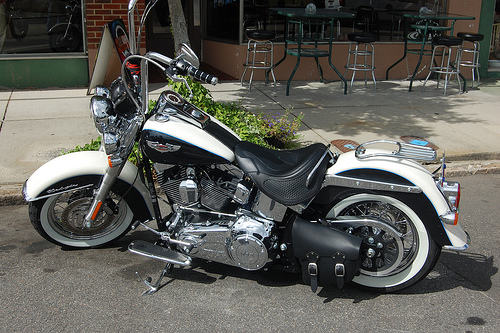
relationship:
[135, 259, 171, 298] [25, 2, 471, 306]
kick stand of motorcycle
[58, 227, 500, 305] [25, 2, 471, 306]
shadow of motorcycle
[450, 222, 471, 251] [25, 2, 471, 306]
fender of motorcycle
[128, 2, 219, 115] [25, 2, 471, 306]
handlebars on motorcycle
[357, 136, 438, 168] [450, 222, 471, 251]
rack on back of fender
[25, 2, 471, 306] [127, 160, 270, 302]
motorcycle has chrome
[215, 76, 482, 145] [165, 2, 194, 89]
shadow of tree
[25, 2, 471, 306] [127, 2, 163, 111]
motorcycle has windshield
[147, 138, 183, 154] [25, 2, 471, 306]
logo on side of motorcycle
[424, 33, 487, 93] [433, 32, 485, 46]
stools with black seats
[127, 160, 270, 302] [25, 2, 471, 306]
chrome on side of motorcycle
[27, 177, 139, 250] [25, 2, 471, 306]
tire in front of motorcycle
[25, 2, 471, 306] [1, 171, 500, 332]
motorcycle on top of street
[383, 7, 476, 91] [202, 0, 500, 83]
table near wall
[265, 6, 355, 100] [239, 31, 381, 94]
table with stools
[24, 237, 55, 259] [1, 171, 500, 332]
spot on top of street